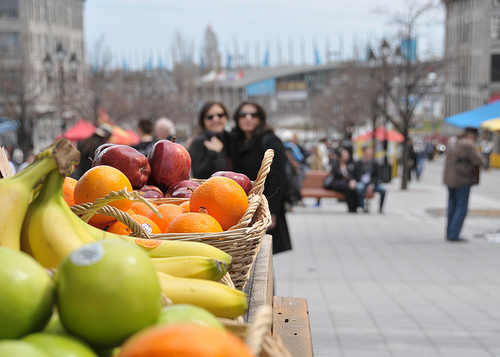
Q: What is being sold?
A: Fruit.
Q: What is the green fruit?
A: Apples.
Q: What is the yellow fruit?
A: Bananas.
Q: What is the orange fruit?
A: Oranges.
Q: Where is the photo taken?
A: On the sidewalk.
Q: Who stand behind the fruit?
A: Two women.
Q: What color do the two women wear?
A: Black.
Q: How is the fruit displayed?
A: In baskets.